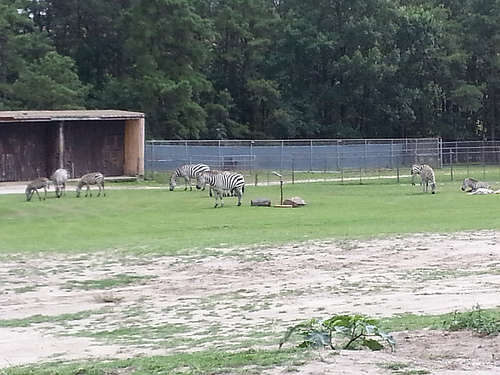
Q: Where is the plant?
A: Pasture.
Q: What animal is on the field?
A: Zeba.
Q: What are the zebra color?
A: White and black.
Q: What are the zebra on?
A: Field.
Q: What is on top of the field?
A: Grass.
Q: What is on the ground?
A: Dirt and grass.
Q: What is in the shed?
A: Zebra's.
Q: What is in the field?
A: Zebra's.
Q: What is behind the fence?
A: Green trees.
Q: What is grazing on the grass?
A: Zebra's.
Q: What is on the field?
A: Large group of zebras.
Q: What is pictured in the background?
A: Long metal fence.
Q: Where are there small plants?
A: In the front section of the photo.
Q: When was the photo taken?
A: Daylight hours.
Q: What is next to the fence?
A: A wooden covered structure.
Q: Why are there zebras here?
A: This looks like a zoo.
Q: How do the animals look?
A: Well fed, peaceful.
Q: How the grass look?
A: There are dirt patches on the grass.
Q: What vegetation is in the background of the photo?
A: Tall trees.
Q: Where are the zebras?
A: In front of the shed and fence.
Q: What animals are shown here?
A: Zebras.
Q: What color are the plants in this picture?
A: Green.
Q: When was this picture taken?
A: Daytime.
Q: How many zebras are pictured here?
A: Seven.